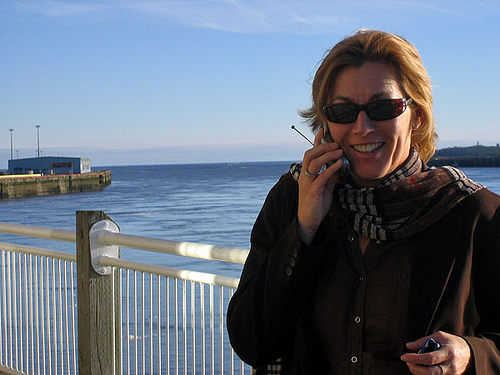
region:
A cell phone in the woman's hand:
[314, 127, 356, 179]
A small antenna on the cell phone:
[289, 121, 321, 150]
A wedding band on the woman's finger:
[301, 169, 321, 183]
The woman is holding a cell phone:
[301, 121, 363, 220]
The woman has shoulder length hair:
[304, 36, 450, 171]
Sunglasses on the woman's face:
[324, 93, 420, 132]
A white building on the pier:
[9, 154, 93, 171]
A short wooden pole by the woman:
[74, 204, 131, 366]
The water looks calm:
[142, 187, 234, 237]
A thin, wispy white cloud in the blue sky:
[193, 8, 303, 38]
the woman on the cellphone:
[191, 25, 477, 372]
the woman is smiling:
[205, 33, 488, 373]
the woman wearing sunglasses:
[271, 23, 445, 200]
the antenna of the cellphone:
[288, 118, 313, 150]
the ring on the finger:
[300, 168, 320, 183]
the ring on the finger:
[433, 362, 448, 374]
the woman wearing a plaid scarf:
[283, 120, 488, 238]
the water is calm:
[156, 173, 220, 238]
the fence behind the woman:
[2, 213, 287, 365]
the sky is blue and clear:
[32, 33, 160, 90]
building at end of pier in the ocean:
[0, 143, 97, 185]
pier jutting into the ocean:
[0, 168, 124, 201]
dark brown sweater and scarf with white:
[221, 151, 493, 366]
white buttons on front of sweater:
[342, 297, 378, 374]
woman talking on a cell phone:
[274, 23, 498, 263]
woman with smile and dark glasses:
[293, 28, 440, 181]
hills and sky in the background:
[429, 135, 498, 163]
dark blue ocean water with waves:
[98, 158, 273, 188]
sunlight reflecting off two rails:
[158, 228, 250, 294]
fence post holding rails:
[74, 208, 127, 372]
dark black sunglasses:
[313, 97, 415, 122]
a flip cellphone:
[300, 114, 355, 177]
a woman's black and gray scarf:
[290, 150, 426, 231]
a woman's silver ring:
[433, 362, 445, 372]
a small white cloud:
[161, 2, 356, 29]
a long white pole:
[95, 221, 250, 271]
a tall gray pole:
[67, 210, 124, 372]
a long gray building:
[3, 155, 90, 173]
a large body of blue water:
[2, 145, 290, 275]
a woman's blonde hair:
[295, 28, 441, 165]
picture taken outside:
[22, 34, 434, 369]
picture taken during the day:
[14, 18, 494, 350]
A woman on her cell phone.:
[182, 5, 494, 359]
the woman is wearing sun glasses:
[320, 90, 414, 125]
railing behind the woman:
[78, 208, 223, 370]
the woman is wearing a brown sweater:
[411, 224, 463, 321]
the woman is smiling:
[350, 133, 390, 163]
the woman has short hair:
[308, 20, 413, 78]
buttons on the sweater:
[331, 238, 382, 373]